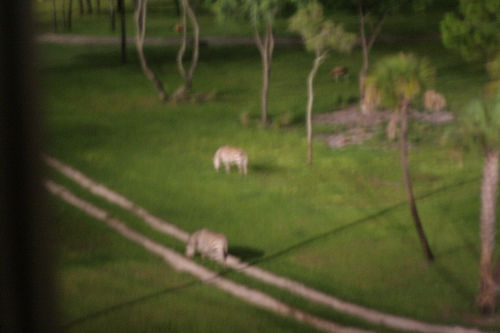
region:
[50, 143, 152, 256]
dirt vehicle path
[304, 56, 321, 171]
brown tree trunk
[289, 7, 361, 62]
tree with small green leaves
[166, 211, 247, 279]
out of focus zebra grazing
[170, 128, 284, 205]
animal standing in green field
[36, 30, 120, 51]
a dirt path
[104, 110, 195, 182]
a field with green grass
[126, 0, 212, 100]
a crooked tree trunk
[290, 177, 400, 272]
shadow cast on ground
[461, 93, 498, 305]
a palm tree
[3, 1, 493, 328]
the picture is blurry.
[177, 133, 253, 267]
Two animals grazing.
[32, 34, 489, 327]
The grass is green.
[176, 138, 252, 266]
The animals are brown.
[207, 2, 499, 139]
The leaves on the trees are green.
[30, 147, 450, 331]
The logs are brown.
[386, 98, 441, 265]
The tree trunk is brown.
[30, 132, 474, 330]
Two logs laying next to each other.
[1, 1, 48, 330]
Shadow along the side.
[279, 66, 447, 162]
Pond in the grass.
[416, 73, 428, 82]
leaf of a tree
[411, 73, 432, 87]
leaves of a twig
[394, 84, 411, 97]
a small twig of a tree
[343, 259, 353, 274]
a green grass vegetation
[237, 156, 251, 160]
a white animal on grass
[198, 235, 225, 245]
a sheep feeding on grass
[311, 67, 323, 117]
stem of a tree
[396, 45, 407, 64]
branches of a tree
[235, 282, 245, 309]
white part on grass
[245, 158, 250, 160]
back of a sheep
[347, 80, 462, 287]
the tree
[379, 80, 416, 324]
the tree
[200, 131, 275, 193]
zebra in a field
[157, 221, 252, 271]
zebra in a field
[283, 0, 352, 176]
large tree in a field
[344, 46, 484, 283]
large tree in a field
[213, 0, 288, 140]
large tree in a field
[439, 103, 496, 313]
large tree in a field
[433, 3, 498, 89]
large tree in a field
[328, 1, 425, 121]
large tree in a field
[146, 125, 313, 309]
two zebras in a field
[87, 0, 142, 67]
a large tree trunk